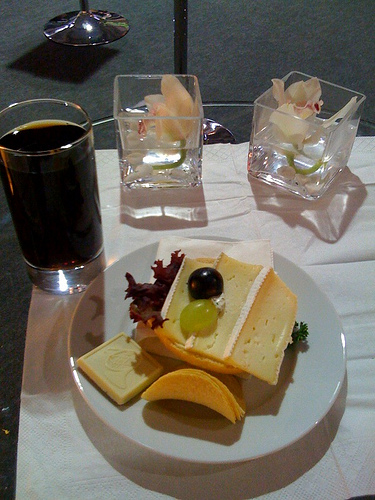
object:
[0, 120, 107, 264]
soda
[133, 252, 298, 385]
cheese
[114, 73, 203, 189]
glass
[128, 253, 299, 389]
sandwich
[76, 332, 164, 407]
cheese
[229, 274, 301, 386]
slice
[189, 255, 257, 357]
slice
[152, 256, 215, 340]
slice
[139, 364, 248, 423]
chips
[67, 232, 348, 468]
plate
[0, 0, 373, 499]
table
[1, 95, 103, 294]
glass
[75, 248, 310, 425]
food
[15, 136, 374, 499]
napkin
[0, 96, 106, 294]
glasses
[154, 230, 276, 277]
napkin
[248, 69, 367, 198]
glass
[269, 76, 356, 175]
orchid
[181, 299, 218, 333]
grape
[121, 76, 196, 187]
flower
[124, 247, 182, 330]
lettuce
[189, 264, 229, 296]
grape